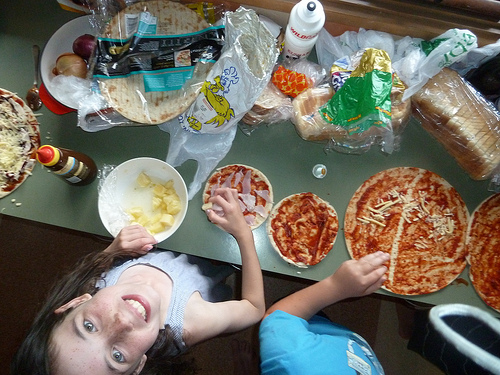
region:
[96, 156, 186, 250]
a bowl with food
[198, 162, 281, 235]
a round uncooked pizza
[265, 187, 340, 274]
a round uncooked pizza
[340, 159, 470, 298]
a round uncooked pizza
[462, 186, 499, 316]
a round uncooked pizza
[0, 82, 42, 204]
a round uncooked pizza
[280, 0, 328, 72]
a white bottle on a table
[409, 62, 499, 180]
a bag of bread on a table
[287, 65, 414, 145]
a bad of bread on a table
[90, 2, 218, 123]
a bag of pizza crust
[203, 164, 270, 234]
Pizza with some toppings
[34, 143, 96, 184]
A bottle of sauce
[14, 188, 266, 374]
A girl making a pizza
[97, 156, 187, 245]
A plate with food on it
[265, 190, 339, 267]
A pizza with sauce on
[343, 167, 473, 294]
A circle of dough with sauce on it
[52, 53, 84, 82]
An onion in a bowl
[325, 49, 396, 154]
A plastic bag on a table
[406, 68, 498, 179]
A loaf of bread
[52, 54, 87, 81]
A red and yellow onion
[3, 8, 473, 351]
the view from above of kids making pizza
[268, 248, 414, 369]
the hand of a child making pizza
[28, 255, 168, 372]
the face of a girl looking up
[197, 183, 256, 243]
the hand of a girl making pizza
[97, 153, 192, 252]
a bowl of cheese cubes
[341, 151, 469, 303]
a plate of pizza fixings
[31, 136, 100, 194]
a bottle of chocolate sauce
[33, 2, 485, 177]
several plastic bags full of food items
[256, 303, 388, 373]
the blue shirt of a child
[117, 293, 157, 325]
the smile of a young girl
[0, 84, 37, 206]
part of finished pizza pie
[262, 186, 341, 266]
pizza pie with just tomato sauce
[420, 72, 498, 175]
white sliced loaf of bred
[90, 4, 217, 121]
round pita bread in plastic wrapping.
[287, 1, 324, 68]
white liquid container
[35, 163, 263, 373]
girl putting toppings on pizza pie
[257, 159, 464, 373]
person putting cheese on pizza pie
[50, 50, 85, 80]
oignion on white plate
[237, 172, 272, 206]
sliced ham on pizza pie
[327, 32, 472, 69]
empty plastic bags on counter top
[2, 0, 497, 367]
it's a food-making party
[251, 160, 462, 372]
a child in a blue top is making a pizza tortilla thing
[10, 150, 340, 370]
the girl is decorating tortillas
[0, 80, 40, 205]
a cheese pizza ready for baking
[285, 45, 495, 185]
two loaves of bread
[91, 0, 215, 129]
a package of really big flour tortillas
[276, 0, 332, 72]
a sport sipper bottle in the middle of the food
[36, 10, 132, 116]
a couple of onions in a bowl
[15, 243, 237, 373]
the girl is wearing a sleeveless blue top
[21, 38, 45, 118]
spoon used to spread the sauce around on the tortillas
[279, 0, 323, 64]
white plastic water bottle with a black spout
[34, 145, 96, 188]
bottle with a red top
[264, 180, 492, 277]
Pizza on the table.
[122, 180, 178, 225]
cheese in the bowl.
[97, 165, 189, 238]
The bowl is white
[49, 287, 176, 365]
The girl is looking up.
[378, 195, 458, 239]
Cheese on the pizza.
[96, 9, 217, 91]
The bag is plastic.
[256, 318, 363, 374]
The shirt is blue.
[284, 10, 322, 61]
Water bottle on counter.